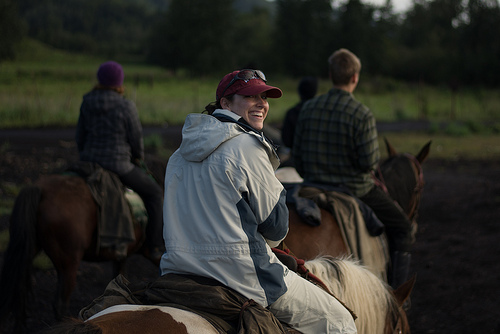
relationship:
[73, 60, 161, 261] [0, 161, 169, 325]
person riding a horse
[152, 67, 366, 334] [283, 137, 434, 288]
people riding a horse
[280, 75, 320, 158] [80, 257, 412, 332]
person riding a horse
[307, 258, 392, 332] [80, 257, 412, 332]
mane of horse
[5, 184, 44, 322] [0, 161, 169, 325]
tail of horse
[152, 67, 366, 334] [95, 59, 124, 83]
people wearing a hat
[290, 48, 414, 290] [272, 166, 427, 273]
guy riding a horse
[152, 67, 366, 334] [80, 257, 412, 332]
people on a horse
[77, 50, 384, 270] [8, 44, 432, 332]
people on horses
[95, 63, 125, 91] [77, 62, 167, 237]
hat on a woman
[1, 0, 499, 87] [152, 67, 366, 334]
trees in front of people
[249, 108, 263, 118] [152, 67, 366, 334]
smile on people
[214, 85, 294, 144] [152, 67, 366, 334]
face of people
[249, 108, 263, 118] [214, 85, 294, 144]
smile on face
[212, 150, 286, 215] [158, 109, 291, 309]
line on jacket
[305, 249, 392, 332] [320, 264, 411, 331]
mane on head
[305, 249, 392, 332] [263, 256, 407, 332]
mane on horse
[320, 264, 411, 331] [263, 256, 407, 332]
head of horse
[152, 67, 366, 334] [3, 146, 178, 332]
people on a horse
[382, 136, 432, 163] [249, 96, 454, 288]
ears on a horse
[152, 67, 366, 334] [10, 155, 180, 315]
people on a horses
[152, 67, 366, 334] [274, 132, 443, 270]
people on a horses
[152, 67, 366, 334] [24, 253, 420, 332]
people on a horses